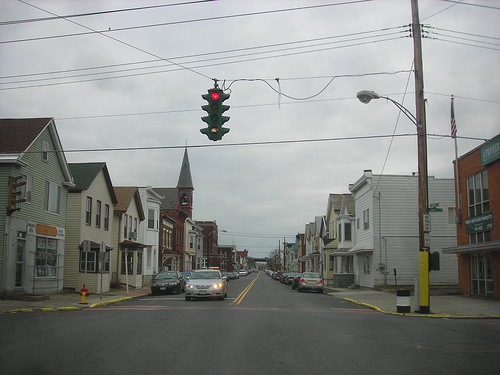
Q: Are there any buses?
A: No, there are no buses.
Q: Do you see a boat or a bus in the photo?
A: No, there are no buses or boats.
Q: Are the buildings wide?
A: Yes, the buildings are wide.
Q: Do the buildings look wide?
A: Yes, the buildings are wide.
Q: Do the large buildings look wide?
A: Yes, the buildings are wide.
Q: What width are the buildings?
A: The buildings are wide.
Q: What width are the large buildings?
A: The buildings are wide.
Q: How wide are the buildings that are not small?
A: The buildings are wide.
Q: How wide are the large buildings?
A: The buildings are wide.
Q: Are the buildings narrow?
A: No, the buildings are wide.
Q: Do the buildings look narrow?
A: No, the buildings are wide.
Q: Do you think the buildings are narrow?
A: No, the buildings are wide.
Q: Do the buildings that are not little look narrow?
A: No, the buildings are wide.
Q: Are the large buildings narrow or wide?
A: The buildings are wide.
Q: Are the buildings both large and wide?
A: Yes, the buildings are large and wide.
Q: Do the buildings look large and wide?
A: Yes, the buildings are large and wide.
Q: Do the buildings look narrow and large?
A: No, the buildings are large but wide.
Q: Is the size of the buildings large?
A: Yes, the buildings are large.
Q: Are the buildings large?
A: Yes, the buildings are large.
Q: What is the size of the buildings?
A: The buildings are large.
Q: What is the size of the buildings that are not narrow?
A: The buildings are large.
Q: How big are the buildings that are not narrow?
A: The buildings are large.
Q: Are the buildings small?
A: No, the buildings are large.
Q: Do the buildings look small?
A: No, the buildings are large.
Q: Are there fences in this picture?
A: No, there are no fences.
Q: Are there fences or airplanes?
A: No, there are no fences or airplanes.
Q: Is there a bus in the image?
A: No, there are no buses.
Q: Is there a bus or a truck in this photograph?
A: No, there are no buses or trucks.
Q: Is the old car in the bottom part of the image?
A: Yes, the car is in the bottom of the image.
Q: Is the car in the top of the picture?
A: No, the car is in the bottom of the image.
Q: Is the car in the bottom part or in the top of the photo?
A: The car is in the bottom of the image.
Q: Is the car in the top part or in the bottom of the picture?
A: The car is in the bottom of the image.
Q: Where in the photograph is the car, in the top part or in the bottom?
A: The car is in the bottom of the image.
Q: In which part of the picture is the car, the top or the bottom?
A: The car is in the bottom of the image.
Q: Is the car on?
A: Yes, the car is on.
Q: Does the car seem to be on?
A: Yes, the car is on.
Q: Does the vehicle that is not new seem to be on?
A: Yes, the car is on.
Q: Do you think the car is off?
A: No, the car is on.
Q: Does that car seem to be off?
A: No, the car is on.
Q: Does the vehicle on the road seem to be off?
A: No, the car is on.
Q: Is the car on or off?
A: The car is on.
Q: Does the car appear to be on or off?
A: The car is on.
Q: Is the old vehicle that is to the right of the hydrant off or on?
A: The car is on.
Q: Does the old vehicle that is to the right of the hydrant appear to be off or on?
A: The car is on.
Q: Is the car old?
A: Yes, the car is old.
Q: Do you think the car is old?
A: Yes, the car is old.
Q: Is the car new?
A: No, the car is old.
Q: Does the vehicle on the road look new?
A: No, the car is old.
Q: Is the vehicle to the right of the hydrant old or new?
A: The car is old.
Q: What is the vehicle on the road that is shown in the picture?
A: The vehicle is a car.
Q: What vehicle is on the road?
A: The vehicle is a car.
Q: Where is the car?
A: The car is on the road.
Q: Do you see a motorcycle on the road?
A: No, there is a car on the road.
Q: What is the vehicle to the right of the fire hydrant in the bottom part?
A: The vehicle is a car.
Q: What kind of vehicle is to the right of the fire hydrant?
A: The vehicle is a car.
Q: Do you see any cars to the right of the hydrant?
A: Yes, there is a car to the right of the hydrant.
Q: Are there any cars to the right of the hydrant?
A: Yes, there is a car to the right of the hydrant.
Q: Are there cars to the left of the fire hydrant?
A: No, the car is to the right of the fire hydrant.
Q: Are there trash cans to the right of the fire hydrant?
A: No, there is a car to the right of the fire hydrant.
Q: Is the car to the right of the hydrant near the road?
A: Yes, the car is to the right of the fire hydrant.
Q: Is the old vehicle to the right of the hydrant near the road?
A: Yes, the car is to the right of the fire hydrant.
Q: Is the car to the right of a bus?
A: No, the car is to the right of the fire hydrant.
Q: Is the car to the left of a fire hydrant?
A: No, the car is to the right of a fire hydrant.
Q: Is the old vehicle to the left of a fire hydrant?
A: No, the car is to the right of a fire hydrant.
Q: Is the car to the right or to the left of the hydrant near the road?
A: The car is to the right of the hydrant.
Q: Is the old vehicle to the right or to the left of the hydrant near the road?
A: The car is to the right of the hydrant.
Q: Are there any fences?
A: No, there are no fences.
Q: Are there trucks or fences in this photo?
A: No, there are no fences or trucks.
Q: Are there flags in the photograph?
A: Yes, there is a flag.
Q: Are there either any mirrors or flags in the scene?
A: Yes, there is a flag.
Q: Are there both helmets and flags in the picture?
A: No, there is a flag but no helmets.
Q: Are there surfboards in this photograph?
A: No, there are no surfboards.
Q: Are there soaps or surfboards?
A: No, there are no surfboards or soaps.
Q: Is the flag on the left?
A: No, the flag is on the right of the image.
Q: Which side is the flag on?
A: The flag is on the right of the image.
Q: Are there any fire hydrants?
A: Yes, there is a fire hydrant.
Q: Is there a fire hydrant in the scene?
A: Yes, there is a fire hydrant.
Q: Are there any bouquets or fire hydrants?
A: Yes, there is a fire hydrant.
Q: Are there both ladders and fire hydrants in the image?
A: No, there is a fire hydrant but no ladders.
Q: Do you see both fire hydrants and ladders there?
A: No, there is a fire hydrant but no ladders.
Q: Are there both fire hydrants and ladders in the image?
A: No, there is a fire hydrant but no ladders.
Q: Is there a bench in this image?
A: No, there are no benches.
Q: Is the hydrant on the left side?
A: Yes, the hydrant is on the left of the image.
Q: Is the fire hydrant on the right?
A: No, the fire hydrant is on the left of the image.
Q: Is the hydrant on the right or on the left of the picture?
A: The hydrant is on the left of the image.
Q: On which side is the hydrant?
A: The hydrant is on the left of the image.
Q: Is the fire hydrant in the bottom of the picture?
A: Yes, the fire hydrant is in the bottom of the image.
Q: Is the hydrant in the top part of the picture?
A: No, the hydrant is in the bottom of the image.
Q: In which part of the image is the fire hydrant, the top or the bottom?
A: The fire hydrant is in the bottom of the image.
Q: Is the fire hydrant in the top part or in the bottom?
A: The fire hydrant is in the bottom of the image.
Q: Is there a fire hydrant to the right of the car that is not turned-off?
A: No, the fire hydrant is to the left of the car.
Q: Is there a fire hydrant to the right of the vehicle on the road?
A: No, the fire hydrant is to the left of the car.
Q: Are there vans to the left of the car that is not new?
A: No, there is a fire hydrant to the left of the car.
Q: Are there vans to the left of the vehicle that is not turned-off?
A: No, there is a fire hydrant to the left of the car.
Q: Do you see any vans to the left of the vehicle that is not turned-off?
A: No, there is a fire hydrant to the left of the car.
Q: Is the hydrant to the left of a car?
A: Yes, the hydrant is to the left of a car.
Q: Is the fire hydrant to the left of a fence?
A: No, the fire hydrant is to the left of a car.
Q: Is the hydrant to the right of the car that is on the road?
A: No, the hydrant is to the left of the car.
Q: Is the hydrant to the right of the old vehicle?
A: No, the hydrant is to the left of the car.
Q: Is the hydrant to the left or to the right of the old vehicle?
A: The hydrant is to the left of the car.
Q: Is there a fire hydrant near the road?
A: Yes, there is a fire hydrant near the road.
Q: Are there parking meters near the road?
A: No, there is a fire hydrant near the road.